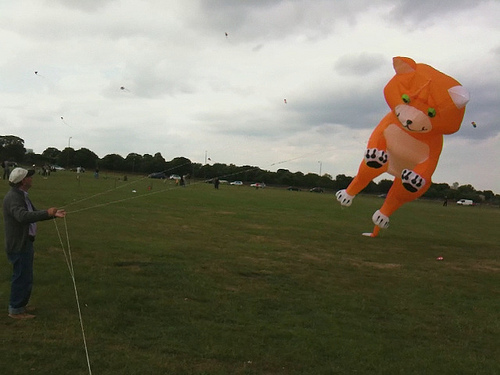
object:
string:
[62, 212, 93, 375]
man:
[5, 164, 65, 319]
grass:
[0, 162, 499, 373]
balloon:
[332, 51, 471, 236]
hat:
[8, 163, 35, 188]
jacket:
[4, 187, 57, 258]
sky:
[0, 2, 499, 194]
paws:
[362, 145, 391, 169]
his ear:
[446, 81, 471, 109]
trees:
[0, 131, 499, 205]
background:
[0, 0, 495, 375]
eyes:
[426, 105, 438, 119]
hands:
[47, 207, 57, 215]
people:
[214, 176, 221, 191]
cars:
[250, 182, 266, 188]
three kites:
[29, 66, 128, 128]